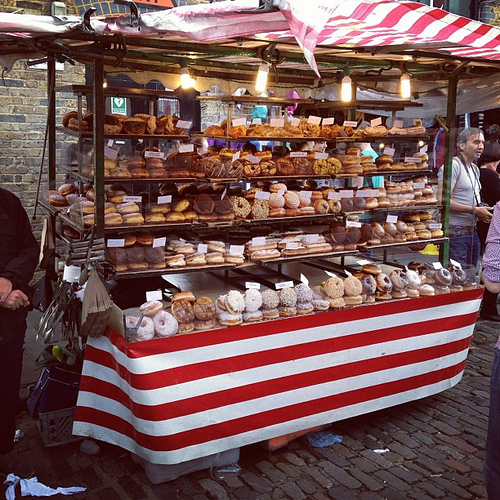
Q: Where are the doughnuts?
A: At the market.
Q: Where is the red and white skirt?
A: On the stand.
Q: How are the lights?
A: Hanging.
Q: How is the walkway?
A: Brick.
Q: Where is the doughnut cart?
A: On street.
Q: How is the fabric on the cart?
A: Striped.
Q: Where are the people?
A: Next to the cart.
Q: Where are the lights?
A: Above the cart.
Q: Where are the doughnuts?
A: On cart.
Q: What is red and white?
A: Awning covering.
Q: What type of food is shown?
A: Pastries.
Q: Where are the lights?
A: Hanging on the ceiling of the cart.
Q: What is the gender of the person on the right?
A: Male.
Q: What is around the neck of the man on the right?
A: Camera.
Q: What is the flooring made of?
A: Cobblestone.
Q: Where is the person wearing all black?
A: Left side of the cart.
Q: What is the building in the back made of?
A: Brick.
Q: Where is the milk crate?
A: Left side behind the cart.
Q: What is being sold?
A: Doughnuts.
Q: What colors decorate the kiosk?
A: Red and white.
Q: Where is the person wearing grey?
A: The right.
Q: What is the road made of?
A: Bricks.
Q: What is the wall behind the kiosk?
A: Brick.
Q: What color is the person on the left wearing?
A: Black.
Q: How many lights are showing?
A: 4.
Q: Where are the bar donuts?
A: The second shelf.